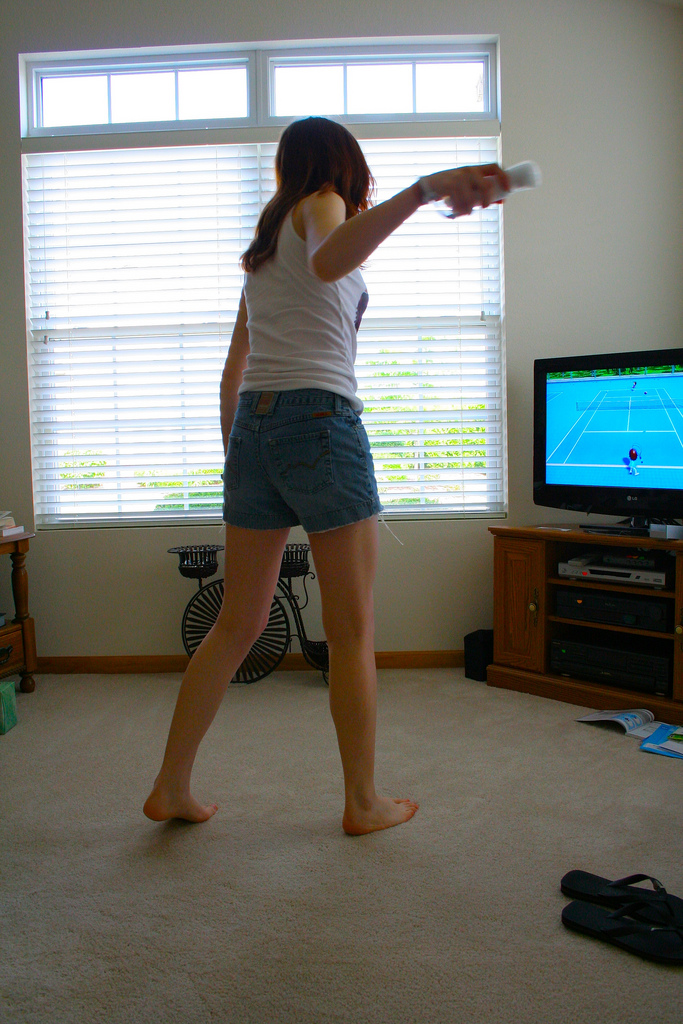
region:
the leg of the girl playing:
[302, 485, 381, 804]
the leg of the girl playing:
[143, 515, 295, 788]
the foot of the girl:
[339, 788, 416, 833]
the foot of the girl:
[143, 787, 217, 823]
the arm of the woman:
[304, 190, 431, 275]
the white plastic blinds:
[21, 130, 503, 523]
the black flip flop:
[559, 900, 678, 959]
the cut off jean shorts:
[220, 387, 381, 535]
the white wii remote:
[436, 154, 539, 223]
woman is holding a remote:
[420, 150, 544, 222]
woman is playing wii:
[137, 109, 538, 845]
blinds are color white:
[16, 135, 524, 536]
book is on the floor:
[567, 696, 667, 739]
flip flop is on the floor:
[562, 900, 682, 976]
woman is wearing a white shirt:
[244, 202, 369, 405]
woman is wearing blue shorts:
[222, 390, 381, 533]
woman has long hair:
[234, 111, 375, 278]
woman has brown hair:
[234, 116, 372, 287]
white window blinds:
[9, 134, 505, 513]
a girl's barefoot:
[330, 780, 430, 841]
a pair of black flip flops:
[557, 860, 678, 966]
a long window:
[12, 45, 492, 140]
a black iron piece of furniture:
[158, 532, 322, 691]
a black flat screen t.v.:
[525, 340, 681, 522]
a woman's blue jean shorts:
[227, 384, 392, 533]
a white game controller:
[444, 150, 548, 212]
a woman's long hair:
[240, 103, 380, 278]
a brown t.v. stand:
[475, 512, 680, 717]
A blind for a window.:
[20, 166, 506, 191]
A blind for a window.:
[22, 241, 498, 257]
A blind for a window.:
[25, 268, 502, 292]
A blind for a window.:
[29, 313, 510, 348]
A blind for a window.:
[31, 357, 507, 392]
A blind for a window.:
[39, 441, 504, 469]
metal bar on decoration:
[268, 622, 287, 634]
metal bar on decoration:
[257, 640, 286, 661]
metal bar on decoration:
[249, 651, 271, 677]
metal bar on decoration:
[242, 662, 259, 682]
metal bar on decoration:
[208, 580, 222, 604]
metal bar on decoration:
[192, 593, 216, 620]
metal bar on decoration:
[183, 628, 210, 635]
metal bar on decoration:
[201, 584, 218, 607]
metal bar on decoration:
[188, 595, 216, 618]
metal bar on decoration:
[186, 605, 214, 624]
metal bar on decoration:
[183, 624, 207, 636]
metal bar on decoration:
[184, 637, 198, 653]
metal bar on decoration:
[233, 664, 239, 682]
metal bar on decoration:
[237, 658, 249, 682]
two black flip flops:
[559, 860, 680, 978]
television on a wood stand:
[486, 347, 680, 723]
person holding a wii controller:
[137, 115, 543, 835]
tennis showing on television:
[515, 347, 679, 540]